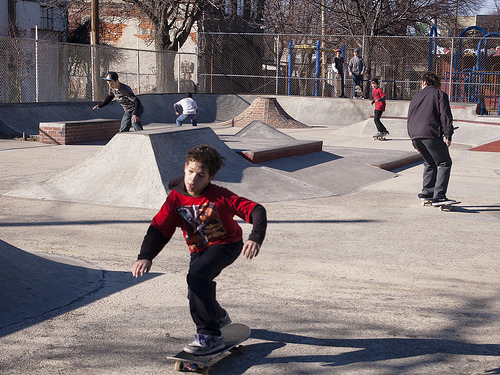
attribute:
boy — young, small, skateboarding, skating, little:
[132, 145, 268, 355]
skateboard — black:
[165, 322, 252, 375]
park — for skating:
[2, 23, 499, 374]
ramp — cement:
[0, 119, 397, 210]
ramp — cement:
[331, 117, 500, 147]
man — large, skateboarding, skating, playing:
[406, 72, 456, 208]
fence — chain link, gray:
[0, 23, 499, 116]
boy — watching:
[331, 49, 346, 99]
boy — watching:
[347, 48, 366, 101]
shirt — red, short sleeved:
[149, 184, 258, 255]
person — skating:
[92, 70, 144, 133]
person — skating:
[172, 92, 202, 125]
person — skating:
[368, 76, 389, 136]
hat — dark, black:
[101, 72, 119, 83]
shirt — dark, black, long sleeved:
[406, 84, 454, 140]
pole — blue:
[286, 41, 294, 97]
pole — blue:
[314, 39, 321, 99]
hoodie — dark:
[136, 176, 267, 261]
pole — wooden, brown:
[88, 0, 99, 102]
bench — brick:
[37, 118, 123, 146]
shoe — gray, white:
[183, 332, 227, 356]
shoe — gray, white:
[216, 315, 232, 328]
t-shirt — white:
[175, 97, 201, 115]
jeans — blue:
[175, 112, 198, 127]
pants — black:
[186, 238, 244, 336]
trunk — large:
[155, 50, 178, 94]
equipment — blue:
[444, 25, 500, 114]